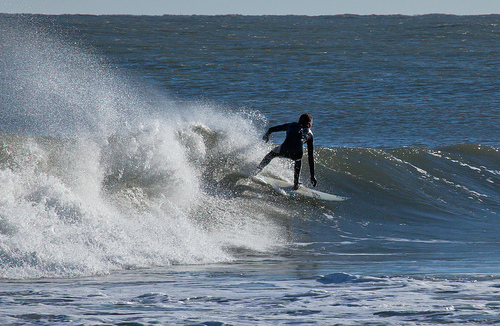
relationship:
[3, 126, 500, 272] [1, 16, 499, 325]
waves in ocean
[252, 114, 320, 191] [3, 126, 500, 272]
person riding surf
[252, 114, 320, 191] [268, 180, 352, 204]
person on top of surfboard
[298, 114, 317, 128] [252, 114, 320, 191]
head of man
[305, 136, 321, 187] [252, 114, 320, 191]
arm of man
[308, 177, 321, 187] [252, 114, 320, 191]
hand of man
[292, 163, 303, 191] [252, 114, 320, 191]
leg of man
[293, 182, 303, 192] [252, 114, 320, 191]
foot of man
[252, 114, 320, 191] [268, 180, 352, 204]
man on surfboard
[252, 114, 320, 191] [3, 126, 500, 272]
surfer riding wave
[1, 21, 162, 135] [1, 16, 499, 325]
splash of water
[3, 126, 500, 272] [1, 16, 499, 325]
wave in ocean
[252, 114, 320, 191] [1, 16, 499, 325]
surfer in ocean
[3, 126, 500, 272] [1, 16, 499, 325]
ripples in ocean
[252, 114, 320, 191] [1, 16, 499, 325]
man in ocean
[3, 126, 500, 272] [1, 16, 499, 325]
wave from ocean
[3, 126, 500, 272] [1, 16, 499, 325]
water of ocean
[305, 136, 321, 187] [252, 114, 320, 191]
arm of surfer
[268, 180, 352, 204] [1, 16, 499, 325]
surfboard in ocean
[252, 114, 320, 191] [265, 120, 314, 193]
person in wetsuit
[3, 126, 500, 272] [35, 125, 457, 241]
water spraying waves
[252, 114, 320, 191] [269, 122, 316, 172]
man wearing wetsuit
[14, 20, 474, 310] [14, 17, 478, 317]
water splashing waves